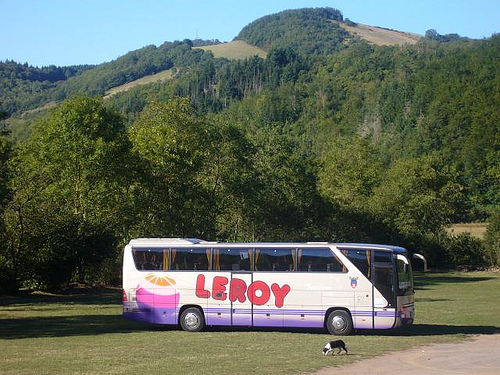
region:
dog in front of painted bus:
[113, 226, 423, 354]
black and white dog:
[303, 336, 400, 367]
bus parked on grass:
[112, 221, 429, 370]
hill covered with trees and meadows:
[18, 16, 499, 171]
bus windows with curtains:
[123, 235, 430, 332]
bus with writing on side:
[119, 227, 415, 339]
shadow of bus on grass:
[7, 238, 413, 337]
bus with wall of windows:
[126, 229, 424, 334]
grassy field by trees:
[0, 120, 499, 373]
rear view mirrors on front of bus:
[383, 220, 435, 330]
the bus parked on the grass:
[122, 236, 414, 336]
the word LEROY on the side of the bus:
[195, 273, 290, 308]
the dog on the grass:
[321, 339, 348, 356]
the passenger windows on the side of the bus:
[130, 244, 348, 273]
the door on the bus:
[373, 262, 397, 328]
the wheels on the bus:
[180, 307, 354, 337]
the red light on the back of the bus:
[120, 288, 127, 303]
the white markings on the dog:
[320, 340, 347, 355]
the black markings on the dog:
[322, 340, 348, 356]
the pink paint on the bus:
[133, 284, 180, 309]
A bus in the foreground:
[113, 219, 421, 339]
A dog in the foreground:
[311, 330, 353, 362]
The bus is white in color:
[120, 221, 425, 340]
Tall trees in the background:
[0, 69, 498, 288]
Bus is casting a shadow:
[376, 314, 499, 344]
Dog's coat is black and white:
[316, 336, 353, 362]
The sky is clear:
[0, 1, 496, 62]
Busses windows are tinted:
[135, 245, 371, 278]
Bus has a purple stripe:
[128, 299, 398, 322]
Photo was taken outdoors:
[1, 0, 494, 372]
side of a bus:
[252, 275, 268, 305]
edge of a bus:
[389, 276, 396, 297]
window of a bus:
[278, 243, 285, 253]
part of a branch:
[76, 169, 90, 190]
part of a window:
[400, 266, 415, 280]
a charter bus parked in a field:
[103, 227, 423, 333]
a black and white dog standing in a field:
[310, 334, 356, 358]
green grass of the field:
[91, 330, 212, 365]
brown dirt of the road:
[418, 354, 493, 374]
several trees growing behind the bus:
[18, 118, 417, 253]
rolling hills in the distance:
[0, 27, 470, 142]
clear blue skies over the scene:
[41, 0, 164, 37]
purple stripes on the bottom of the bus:
[186, 303, 386, 336]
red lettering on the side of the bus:
[187, 267, 292, 312]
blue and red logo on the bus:
[346, 272, 361, 294]